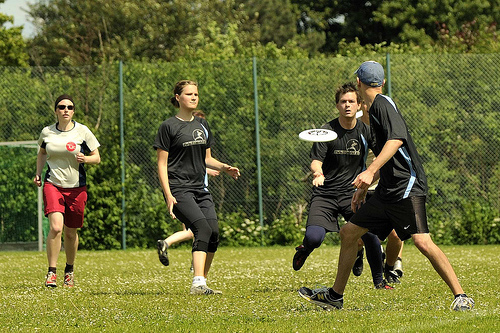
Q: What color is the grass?
A: Green.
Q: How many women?
A: 2.